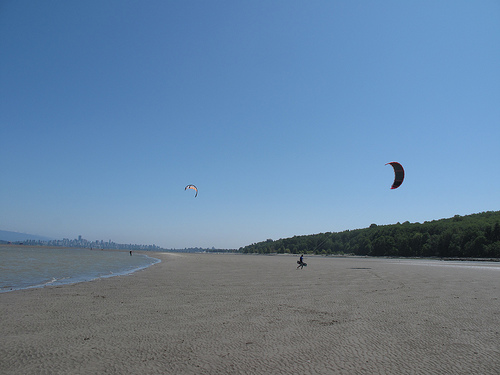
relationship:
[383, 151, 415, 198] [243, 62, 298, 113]
kite in sky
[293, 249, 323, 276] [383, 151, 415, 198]
person flying kite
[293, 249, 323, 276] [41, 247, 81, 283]
person near water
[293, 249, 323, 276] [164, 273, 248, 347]
person on beach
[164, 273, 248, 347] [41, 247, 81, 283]
beach next to water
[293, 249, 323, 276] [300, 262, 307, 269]
person with surboard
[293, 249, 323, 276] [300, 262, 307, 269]
person carrying surboard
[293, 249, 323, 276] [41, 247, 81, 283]
person in water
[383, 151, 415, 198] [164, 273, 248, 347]
kite near beach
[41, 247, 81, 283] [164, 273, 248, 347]
water on beach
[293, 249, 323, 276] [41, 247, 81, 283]
person on water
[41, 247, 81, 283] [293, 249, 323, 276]
water next to person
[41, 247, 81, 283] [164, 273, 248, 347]
water near beach